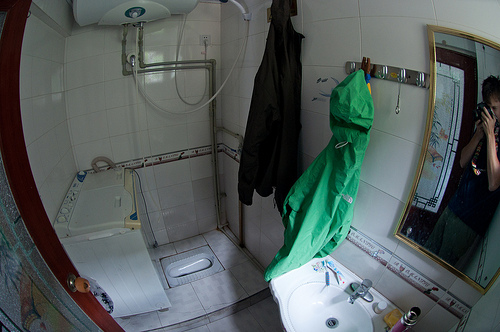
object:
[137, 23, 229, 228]
pipes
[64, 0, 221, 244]
tile wall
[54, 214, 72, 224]
buttons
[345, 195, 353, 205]
brand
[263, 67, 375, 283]
jacket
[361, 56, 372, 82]
hook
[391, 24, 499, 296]
mirror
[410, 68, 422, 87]
stainless hook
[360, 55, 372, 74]
pliers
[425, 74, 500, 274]
man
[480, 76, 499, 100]
hair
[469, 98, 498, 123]
camera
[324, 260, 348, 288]
toothpaste tube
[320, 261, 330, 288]
toothbrush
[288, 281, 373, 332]
sink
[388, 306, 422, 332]
bottle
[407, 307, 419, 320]
lid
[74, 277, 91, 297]
cover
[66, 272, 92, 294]
door knob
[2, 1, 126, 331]
door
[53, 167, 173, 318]
appliance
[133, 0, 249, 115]
cable plugged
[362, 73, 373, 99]
handle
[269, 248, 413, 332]
top view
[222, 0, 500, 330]
wall